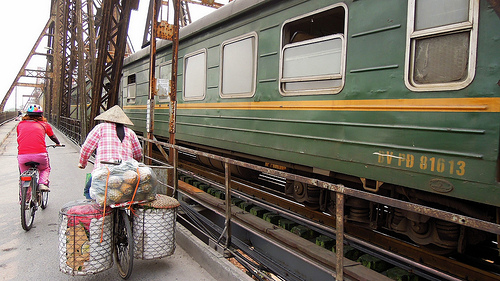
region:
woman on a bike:
[4, 84, 55, 226]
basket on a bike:
[44, 182, 111, 277]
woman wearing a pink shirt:
[13, 113, 53, 155]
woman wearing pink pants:
[15, 150, 54, 195]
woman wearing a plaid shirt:
[79, 127, 136, 176]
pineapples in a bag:
[88, 151, 164, 211]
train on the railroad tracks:
[263, 50, 493, 264]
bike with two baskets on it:
[36, 162, 209, 273]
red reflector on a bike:
[16, 174, 35, 182]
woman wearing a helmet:
[21, 100, 41, 122]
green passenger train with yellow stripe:
[108, 5, 491, 200]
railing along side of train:
[140, 131, 495, 273]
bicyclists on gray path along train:
[0, 101, 225, 272]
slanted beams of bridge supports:
[10, 1, 210, 137]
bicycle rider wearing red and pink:
[10, 96, 55, 231]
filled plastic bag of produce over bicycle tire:
[82, 156, 157, 276]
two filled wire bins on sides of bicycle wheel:
[55, 195, 175, 271]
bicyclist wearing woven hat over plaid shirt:
[75, 100, 135, 165]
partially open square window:
[270, 0, 350, 95]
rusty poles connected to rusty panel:
[142, 1, 177, 163]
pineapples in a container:
[81, 162, 163, 212]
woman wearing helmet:
[21, 91, 48, 126]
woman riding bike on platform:
[10, 96, 48, 243]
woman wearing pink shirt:
[8, 110, 56, 157]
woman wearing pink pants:
[9, 151, 64, 198]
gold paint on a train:
[366, 142, 461, 182]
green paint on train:
[188, 18, 490, 210]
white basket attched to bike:
[134, 209, 196, 244]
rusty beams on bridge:
[53, 2, 118, 92]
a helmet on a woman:
[21, 101, 41, 114]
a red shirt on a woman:
[11, 116, 52, 148]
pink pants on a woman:
[14, 152, 51, 185]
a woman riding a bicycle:
[14, 105, 60, 230]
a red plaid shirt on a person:
[78, 120, 143, 165]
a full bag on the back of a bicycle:
[87, 162, 154, 206]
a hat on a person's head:
[93, 105, 134, 126]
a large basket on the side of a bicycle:
[58, 198, 112, 276]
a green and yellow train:
[106, 0, 496, 240]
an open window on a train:
[274, 5, 350, 96]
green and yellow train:
[177, 22, 492, 169]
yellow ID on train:
[353, 132, 472, 188]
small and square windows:
[174, 12, 353, 95]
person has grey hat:
[86, 97, 134, 128]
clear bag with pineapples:
[82, 157, 147, 213]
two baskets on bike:
[47, 198, 183, 272]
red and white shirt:
[82, 117, 148, 163]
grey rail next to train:
[141, 141, 427, 279]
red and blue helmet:
[15, 104, 62, 121]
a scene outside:
[17, 14, 493, 275]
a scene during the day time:
[9, 14, 478, 246]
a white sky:
[0, 0, 236, 105]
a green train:
[77, 1, 499, 221]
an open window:
[275, 0, 354, 111]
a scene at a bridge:
[3, 5, 498, 278]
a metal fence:
[136, 120, 498, 280]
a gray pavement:
[0, 96, 261, 276]